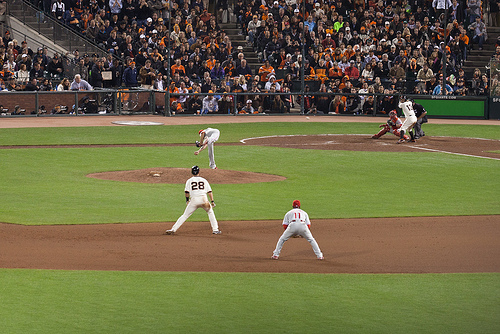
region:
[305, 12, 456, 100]
Baseball fans sitting bleachers.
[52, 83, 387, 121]
Railing running in front of bleachers.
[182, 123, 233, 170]
Pitcher throwing ball to batter.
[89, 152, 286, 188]
Pitcher's mound on baseball diamond.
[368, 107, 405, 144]
Catcher squating behind batter.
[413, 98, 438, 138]
Umpire standing behind catcher.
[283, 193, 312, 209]
Baseball player wearing red cap.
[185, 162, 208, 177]
Player wearing black safety helmet.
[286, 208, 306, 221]
Number 11 printed in red on back of player's shirt.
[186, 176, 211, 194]
Number 28 printed in black on back of player's shirt.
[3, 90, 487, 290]
people playing baseball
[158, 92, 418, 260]
four players wears white uniform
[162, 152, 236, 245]
player has number 28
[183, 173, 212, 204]
number 28 on tee shirt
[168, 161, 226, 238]
player wears balck helmet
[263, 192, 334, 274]
player wears red helmet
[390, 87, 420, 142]
batter is in position to hit a ball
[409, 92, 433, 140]
umpire is crouched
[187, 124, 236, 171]
player in position to throw a ball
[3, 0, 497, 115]
many viewers on bleaches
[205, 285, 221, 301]
Small patch of green grass on the baseball field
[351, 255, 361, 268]
Small patch of brown dirt on baseball field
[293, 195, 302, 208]
Red cap of baseball player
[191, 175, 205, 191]
Number 28 of baseball player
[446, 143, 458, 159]
Solid white line on baseball field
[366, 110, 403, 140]
A catcher squatting down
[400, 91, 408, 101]
Black helmet of catcher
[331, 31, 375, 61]
A group of spectators in the stands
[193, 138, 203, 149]
Catching mitt of pitcher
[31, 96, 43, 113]
Gray fence that protects dugout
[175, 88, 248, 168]
pitcher throwing a pitch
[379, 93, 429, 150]
batter waiting for the pitch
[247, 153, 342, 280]
man playing defense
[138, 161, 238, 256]
man leading off of second base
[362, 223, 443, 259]
brown dirt on the ground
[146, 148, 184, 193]
pitcher's mound on field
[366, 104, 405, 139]
catcher behind the plate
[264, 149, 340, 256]
number eleven on the gray team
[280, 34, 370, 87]
fans in the audience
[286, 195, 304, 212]
hat on the shortstop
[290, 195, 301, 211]
a red cap on a ball player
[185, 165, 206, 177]
a black helmet on a ball player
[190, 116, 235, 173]
a pitcher winding up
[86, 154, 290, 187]
the pitcher's mound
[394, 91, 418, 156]
a batter ready to swing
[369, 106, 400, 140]
a catcher behind a batter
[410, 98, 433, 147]
an umpire behind a catcher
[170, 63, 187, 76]
an orange shirt on a person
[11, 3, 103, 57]
a stairway at a stadium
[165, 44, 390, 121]
a chain link fence